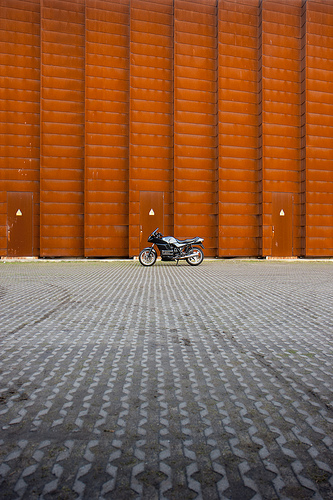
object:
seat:
[176, 236, 199, 244]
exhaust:
[174, 253, 199, 260]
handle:
[147, 227, 163, 242]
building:
[0, 0, 333, 260]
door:
[271, 191, 292, 257]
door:
[139, 191, 164, 256]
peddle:
[175, 258, 178, 266]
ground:
[0, 258, 333, 499]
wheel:
[139, 248, 157, 266]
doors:
[6, 191, 32, 257]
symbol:
[279, 208, 284, 216]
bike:
[139, 227, 205, 266]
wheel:
[185, 246, 204, 266]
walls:
[24, 0, 298, 189]